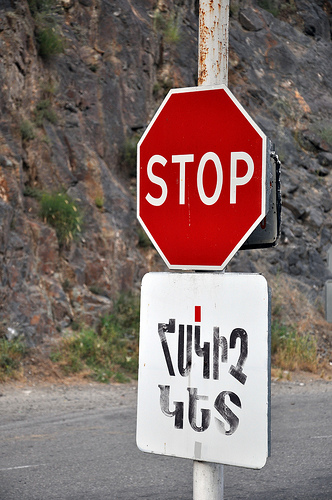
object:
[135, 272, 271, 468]
sign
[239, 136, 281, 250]
sign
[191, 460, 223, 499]
white pole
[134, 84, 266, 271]
octagon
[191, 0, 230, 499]
pole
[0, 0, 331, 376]
rocks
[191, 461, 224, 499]
post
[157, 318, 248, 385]
lettering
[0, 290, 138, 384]
grass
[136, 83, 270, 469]
signs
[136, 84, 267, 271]
sign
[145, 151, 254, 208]
letters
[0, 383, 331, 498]
road